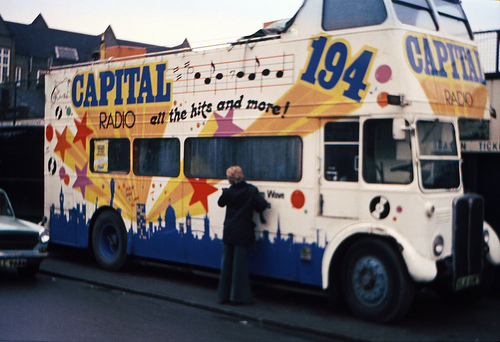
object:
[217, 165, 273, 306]
person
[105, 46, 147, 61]
suitcase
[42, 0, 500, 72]
top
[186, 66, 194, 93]
music note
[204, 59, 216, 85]
music note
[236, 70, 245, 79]
music note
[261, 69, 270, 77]
music note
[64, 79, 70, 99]
music note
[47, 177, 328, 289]
buildings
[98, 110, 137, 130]
sign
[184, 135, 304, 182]
window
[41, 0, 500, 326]
bus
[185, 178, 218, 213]
star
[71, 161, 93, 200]
star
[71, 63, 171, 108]
letters